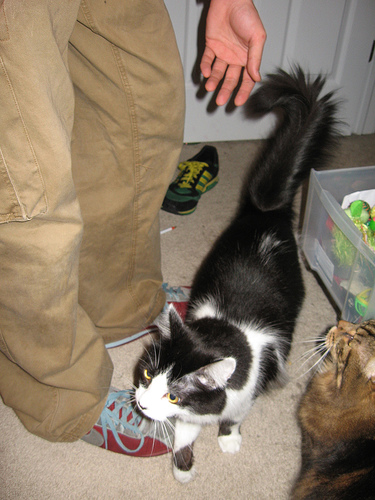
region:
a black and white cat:
[127, 61, 332, 480]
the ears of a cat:
[153, 305, 238, 386]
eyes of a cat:
[138, 365, 189, 401]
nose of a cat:
[136, 397, 147, 409]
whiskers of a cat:
[103, 363, 184, 457]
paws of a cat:
[165, 429, 250, 493]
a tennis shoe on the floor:
[161, 135, 225, 219]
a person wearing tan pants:
[2, 69, 163, 443]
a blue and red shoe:
[75, 377, 185, 469]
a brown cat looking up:
[295, 315, 372, 499]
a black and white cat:
[116, 53, 354, 486]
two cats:
[98, 53, 373, 498]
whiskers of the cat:
[142, 420, 202, 474]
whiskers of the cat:
[278, 330, 332, 394]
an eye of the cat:
[141, 365, 156, 382]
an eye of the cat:
[164, 388, 183, 406]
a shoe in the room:
[158, 142, 221, 218]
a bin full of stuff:
[297, 159, 373, 324]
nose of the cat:
[336, 317, 354, 329]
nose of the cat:
[137, 385, 161, 410]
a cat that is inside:
[117, 171, 358, 480]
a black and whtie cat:
[151, 271, 326, 496]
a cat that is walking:
[96, 264, 358, 499]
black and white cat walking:
[94, 268, 311, 475]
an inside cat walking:
[132, 303, 279, 495]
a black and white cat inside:
[131, 301, 308, 497]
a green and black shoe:
[159, 127, 257, 241]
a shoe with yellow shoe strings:
[147, 112, 279, 238]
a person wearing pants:
[20, 165, 255, 415]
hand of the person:
[177, 6, 283, 105]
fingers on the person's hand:
[184, 41, 273, 110]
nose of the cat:
[127, 392, 160, 420]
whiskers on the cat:
[135, 408, 200, 465]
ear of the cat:
[190, 343, 241, 394]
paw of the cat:
[166, 441, 209, 491]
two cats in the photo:
[112, 272, 369, 479]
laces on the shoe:
[75, 393, 143, 453]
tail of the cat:
[239, 97, 353, 198]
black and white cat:
[112, 71, 341, 476]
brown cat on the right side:
[291, 322, 374, 496]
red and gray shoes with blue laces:
[73, 272, 201, 464]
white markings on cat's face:
[134, 371, 175, 419]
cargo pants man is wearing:
[4, 5, 169, 422]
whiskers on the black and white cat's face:
[117, 391, 192, 466]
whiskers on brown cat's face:
[296, 296, 364, 370]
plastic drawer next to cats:
[307, 159, 374, 329]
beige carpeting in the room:
[5, 132, 366, 491]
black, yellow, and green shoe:
[156, 132, 225, 220]